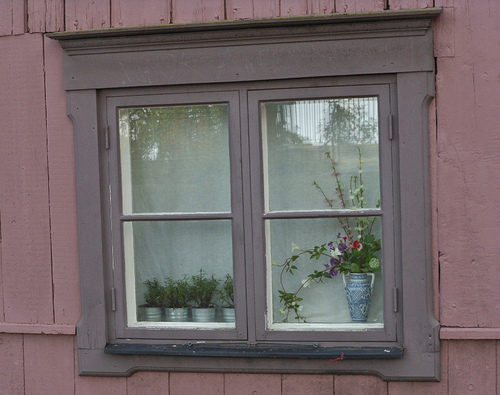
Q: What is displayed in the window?
A: Plants.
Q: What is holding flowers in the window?
A: A vase.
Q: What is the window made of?
A: Glass.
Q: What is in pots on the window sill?
A: Plants.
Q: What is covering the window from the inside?
A: Curtains.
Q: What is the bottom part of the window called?
A: A sill.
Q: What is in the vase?
A: Flowers.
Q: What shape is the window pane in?
A: A rectangle.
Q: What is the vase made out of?
A: Ceramic.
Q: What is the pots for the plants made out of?
A: Metal.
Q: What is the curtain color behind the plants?
A: White.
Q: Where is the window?
A: On the side of the building.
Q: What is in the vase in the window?
A: A green plant.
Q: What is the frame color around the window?
A: Brown.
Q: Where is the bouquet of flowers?
A: In the blue vase in the window.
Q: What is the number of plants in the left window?
A: Four.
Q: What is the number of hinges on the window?
A: Four.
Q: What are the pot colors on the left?
A: Silver.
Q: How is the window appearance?
A: Closed.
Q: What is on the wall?
A: A window.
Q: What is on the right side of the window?
A: A blue vase with flowers.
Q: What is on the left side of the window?
A: Four plants.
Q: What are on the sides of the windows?
A: Hinges.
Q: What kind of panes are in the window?
A: Four small square panes.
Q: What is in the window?
A: Flowers.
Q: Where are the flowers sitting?
A: Window sill.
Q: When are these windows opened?
A: Nice day.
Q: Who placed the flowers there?
A: Homeowner.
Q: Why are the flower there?
A: Sunlight.